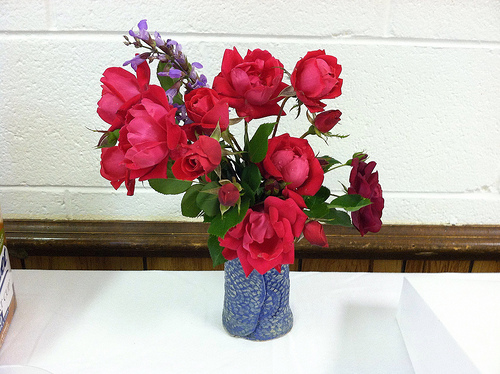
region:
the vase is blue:
[228, 241, 306, 341]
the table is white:
[82, 264, 225, 358]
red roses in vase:
[102, 45, 386, 247]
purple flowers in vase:
[94, 30, 196, 126]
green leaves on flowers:
[192, 122, 347, 225]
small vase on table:
[227, 252, 309, 351]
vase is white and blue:
[220, 251, 305, 344]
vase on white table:
[219, 254, 358, 368]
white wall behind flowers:
[222, 7, 429, 152]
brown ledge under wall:
[94, 188, 496, 270]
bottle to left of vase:
[0, 223, 32, 358]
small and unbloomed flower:
[200, 172, 274, 251]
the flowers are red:
[73, 42, 382, 279]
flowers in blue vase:
[85, 48, 381, 358]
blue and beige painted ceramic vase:
[221, 258, 296, 341]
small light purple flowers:
[122, 18, 209, 121]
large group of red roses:
[96, 45, 385, 275]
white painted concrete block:
[1, 0, 498, 223]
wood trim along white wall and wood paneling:
[0, 218, 499, 258]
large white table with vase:
[1, 268, 498, 372]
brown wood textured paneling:
[0, 248, 498, 273]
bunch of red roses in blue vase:
[83, 45, 385, 342]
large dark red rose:
[348, 158, 385, 238]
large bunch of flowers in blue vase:
[83, 18, 385, 340]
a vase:
[225, 268, 290, 337]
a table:
[315, 285, 368, 355]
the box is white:
[415, 274, 498, 355]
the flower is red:
[270, 136, 315, 188]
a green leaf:
[244, 131, 267, 173]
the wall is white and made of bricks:
[401, 13, 492, 208]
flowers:
[90, 27, 383, 252]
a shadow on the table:
[343, 295, 391, 370]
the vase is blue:
[225, 267, 290, 327]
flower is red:
[233, 218, 293, 268]